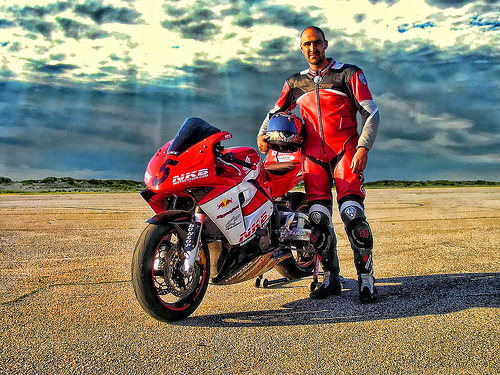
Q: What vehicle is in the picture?
A: Motorcycle.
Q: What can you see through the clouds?
A: The sun.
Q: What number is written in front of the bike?
A: 5.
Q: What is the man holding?
A: Helmet.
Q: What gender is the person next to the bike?
A: Male.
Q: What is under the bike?
A: The ground.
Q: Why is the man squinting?
A: The sun.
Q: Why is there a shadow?
A: The sun.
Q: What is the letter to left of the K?
A: N.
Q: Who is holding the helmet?
A: The man.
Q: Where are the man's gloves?
A: He doesn't have any.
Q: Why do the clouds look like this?
A: Rays of light poking through.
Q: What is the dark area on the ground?
A: Shadows both biker and bike.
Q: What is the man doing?
A: Standing next to motorcycle.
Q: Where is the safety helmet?
A: Biker holding it.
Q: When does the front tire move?
A: When biker rides.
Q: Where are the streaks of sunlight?
A: Breaking through the clouds.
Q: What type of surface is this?
A: Brown and gray gravel.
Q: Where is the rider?
A: Next to the motorcycle.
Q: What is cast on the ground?
A: Shadows.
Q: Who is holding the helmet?
A: The rider.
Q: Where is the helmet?
A: In the rider's hand.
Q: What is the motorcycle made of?
A: Metal.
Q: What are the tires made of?
A: Rubber.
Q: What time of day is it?
A: Day time.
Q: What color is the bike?
A: Red.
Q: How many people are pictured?
A: One.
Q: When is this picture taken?
A: While stopped.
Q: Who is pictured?
A: Biker.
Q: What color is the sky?
A: Blue and white.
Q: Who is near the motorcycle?
A: The man.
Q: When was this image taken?
A: Daytime.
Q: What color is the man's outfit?
A: Red.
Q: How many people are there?
A: One.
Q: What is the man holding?
A: A helmet.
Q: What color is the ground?
A: Brown.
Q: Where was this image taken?
A: On the street.